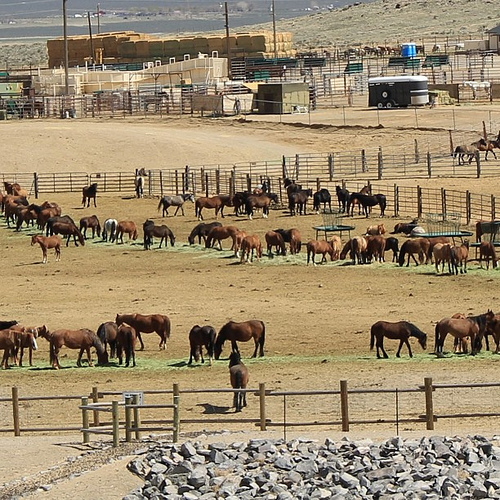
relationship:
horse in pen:
[203, 320, 268, 360] [1, 33, 498, 447]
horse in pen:
[371, 321, 426, 359] [1, 33, 498, 447]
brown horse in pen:
[306, 239, 328, 266] [1, 33, 498, 447]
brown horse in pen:
[114, 214, 144, 252] [7, 144, 478, 309]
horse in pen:
[351, 190, 389, 218] [2, 162, 499, 421]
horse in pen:
[306, 233, 375, 295] [1, 33, 498, 447]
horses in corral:
[187, 221, 302, 268] [0, 167, 499, 419]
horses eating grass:
[6, 164, 498, 397] [4, 211, 498, 278]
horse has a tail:
[99, 219, 113, 242] [107, 220, 117, 241]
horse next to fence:
[203, 303, 278, 365] [1, 380, 499, 431]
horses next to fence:
[202, 175, 387, 227] [91, 152, 352, 196]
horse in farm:
[371, 321, 426, 359] [1, 0, 499, 498]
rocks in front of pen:
[124, 432, 499, 496] [2, 162, 499, 421]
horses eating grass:
[241, 195, 469, 299] [202, 235, 238, 272]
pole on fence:
[10, 386, 19, 436] [1, 376, 497, 437]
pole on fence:
[172, 382, 179, 442] [1, 376, 497, 437]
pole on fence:
[258, 383, 265, 430] [1, 376, 497, 437]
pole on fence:
[339, 379, 349, 430] [1, 376, 497, 437]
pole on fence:
[423, 377, 433, 431] [1, 376, 497, 437]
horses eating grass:
[143, 215, 176, 249] [1, 361, 499, 378]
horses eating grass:
[195, 186, 280, 219] [4, 211, 498, 278]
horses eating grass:
[398, 229, 473, 274] [1, 361, 499, 378]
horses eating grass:
[309, 223, 398, 265] [1, 361, 499, 378]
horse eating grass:
[188, 324, 215, 365] [1, 361, 499, 378]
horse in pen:
[203, 320, 268, 360] [0, 189, 498, 429]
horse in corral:
[203, 320, 268, 360] [0, 95, 499, 419]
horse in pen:
[203, 320, 268, 360] [0, 112, 493, 191]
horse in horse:
[371, 319, 426, 359] [203, 320, 268, 360]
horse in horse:
[188, 324, 215, 365] [203, 320, 268, 360]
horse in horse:
[115, 313, 172, 350] [203, 320, 268, 360]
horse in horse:
[29, 233, 65, 263] [203, 320, 268, 360]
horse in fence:
[220, 346, 250, 409] [3, 378, 482, 457]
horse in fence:
[203, 320, 268, 360] [3, 378, 482, 457]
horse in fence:
[371, 321, 426, 359] [3, 378, 482, 457]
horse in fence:
[115, 313, 172, 350] [3, 378, 482, 457]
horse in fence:
[48, 328, 109, 368] [3, 378, 482, 457]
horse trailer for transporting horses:
[367, 75, 429, 110] [367, 317, 426, 358]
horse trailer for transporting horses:
[367, 75, 429, 110] [433, 312, 480, 359]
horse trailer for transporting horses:
[367, 75, 429, 110] [213, 314, 268, 358]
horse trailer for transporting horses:
[367, 75, 429, 110] [187, 323, 217, 364]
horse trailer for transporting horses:
[367, 75, 429, 110] [224, 347, 249, 413]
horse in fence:
[371, 321, 426, 359] [4, 160, 484, 443]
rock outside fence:
[180, 440, 195, 455] [1, 377, 499, 447]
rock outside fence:
[257, 442, 274, 452] [1, 377, 499, 447]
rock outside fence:
[207, 450, 225, 465] [1, 377, 499, 447]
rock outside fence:
[339, 472, 359, 489] [1, 377, 499, 447]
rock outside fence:
[354, 447, 370, 454] [1, 377, 499, 447]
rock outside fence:
[432, 440, 455, 456] [1, 377, 499, 447]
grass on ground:
[1, 351, 498, 369] [249, 350, 289, 362]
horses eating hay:
[0, 177, 480, 267] [164, 239, 346, 269]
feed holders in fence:
[312, 204, 477, 244] [373, 184, 490, 222]